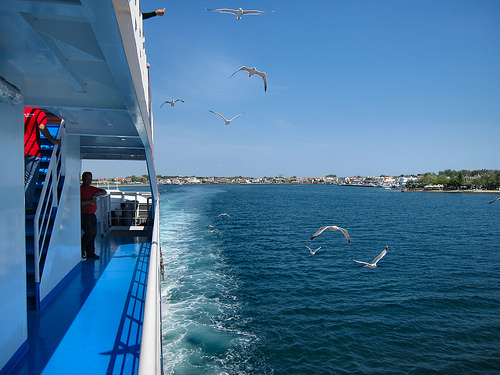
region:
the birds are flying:
[273, 200, 404, 313]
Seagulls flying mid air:
[170, 6, 400, 294]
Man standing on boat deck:
[58, 151, 125, 268]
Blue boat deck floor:
[4, 199, 161, 371]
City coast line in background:
[122, 155, 498, 204]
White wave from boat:
[135, 169, 264, 373]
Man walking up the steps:
[3, 73, 55, 200]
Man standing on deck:
[64, 152, 129, 275]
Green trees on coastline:
[407, 147, 497, 202]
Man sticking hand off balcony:
[125, 0, 179, 37]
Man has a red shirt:
[15, 84, 60, 164]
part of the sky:
[378, 40, 458, 103]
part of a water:
[350, 307, 406, 355]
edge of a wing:
[346, 256, 365, 270]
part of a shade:
[101, 317, 135, 368]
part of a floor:
[93, 316, 116, 341]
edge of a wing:
[295, 222, 326, 246]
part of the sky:
[324, 75, 405, 181]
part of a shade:
[116, 245, 136, 267]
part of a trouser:
[81, 230, 90, 250]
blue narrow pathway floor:
[33, 288, 135, 373]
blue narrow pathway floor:
[54, 245, 151, 373]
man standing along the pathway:
[78, 167, 108, 257]